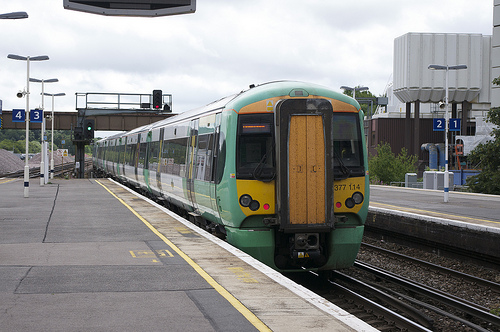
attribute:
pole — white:
[443, 73, 452, 204]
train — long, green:
[84, 78, 371, 274]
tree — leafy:
[461, 80, 498, 195]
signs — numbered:
[431, 116, 461, 135]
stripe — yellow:
[91, 177, 272, 330]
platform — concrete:
[1, 176, 381, 330]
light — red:
[258, 200, 273, 213]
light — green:
[83, 126, 93, 133]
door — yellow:
[288, 115, 326, 225]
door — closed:
[185, 127, 200, 214]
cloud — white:
[1, 1, 493, 111]